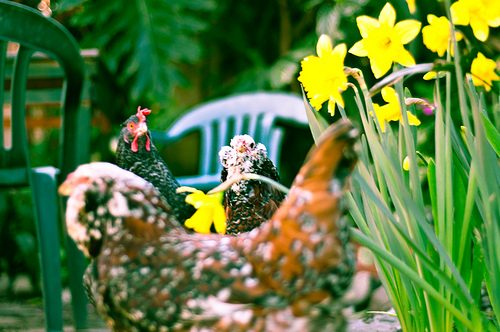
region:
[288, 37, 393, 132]
this is a flower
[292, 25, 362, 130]
the flower is yellow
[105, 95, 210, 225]
this is a rooster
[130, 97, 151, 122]
the rooster is black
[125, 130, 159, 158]
the gobbler is red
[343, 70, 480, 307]
green stems on flowers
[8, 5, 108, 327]
a green plastic chair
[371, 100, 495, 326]
The stems to the flowers are green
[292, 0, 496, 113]
The color of the flowers are yellow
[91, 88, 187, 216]
The chicken in the garden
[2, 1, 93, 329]
The color of the chair is green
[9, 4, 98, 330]
The chair is sitting at the table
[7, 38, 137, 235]
The table is the color green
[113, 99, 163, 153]
The head of the chicken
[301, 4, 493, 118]
The flowers have bloomed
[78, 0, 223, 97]
The leaf on the tree is green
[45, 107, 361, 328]
the chicken is in profile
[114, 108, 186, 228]
the chicken is looking left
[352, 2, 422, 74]
the flower is yellow in color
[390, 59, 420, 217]
the stem is green in color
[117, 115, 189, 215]
the chicken has black feathers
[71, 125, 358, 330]
the chicken has brown feathers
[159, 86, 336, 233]
a chair is in the background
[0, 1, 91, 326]
the chair is made of plastic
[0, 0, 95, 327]
the chair is green in color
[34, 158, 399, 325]
a roster in front of two others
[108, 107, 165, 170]
a roster beside a chair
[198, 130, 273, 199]
a roster beside another roster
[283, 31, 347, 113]
the bloom of a buttercup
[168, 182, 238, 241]
the bloom of a buttercup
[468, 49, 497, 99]
the bloom of a buttercup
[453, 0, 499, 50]
the bloom of a buttercup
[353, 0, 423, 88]
the bloom of a buttercup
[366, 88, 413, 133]
the bloom of a buttercup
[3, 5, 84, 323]
the back of a plastic chair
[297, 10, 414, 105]
the flowers are yellow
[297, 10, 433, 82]
the flowers are yellow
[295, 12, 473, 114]
the flowers are yellow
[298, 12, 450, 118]
the flowers are yellow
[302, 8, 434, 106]
the flowers are yellow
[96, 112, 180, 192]
the rooster is black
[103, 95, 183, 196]
the rooster is black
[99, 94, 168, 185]
the rooster is black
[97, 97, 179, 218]
the rooster is black